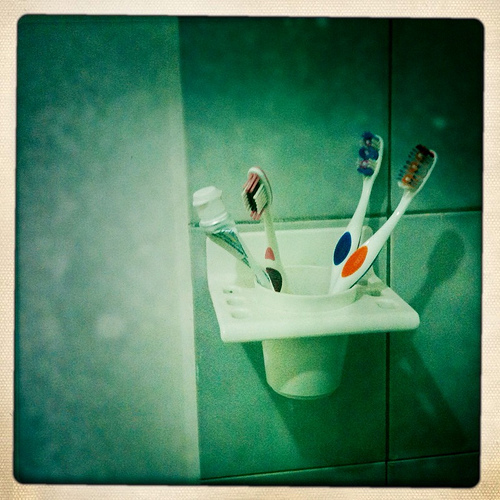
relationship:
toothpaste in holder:
[182, 184, 266, 294] [195, 229, 416, 411]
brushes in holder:
[237, 125, 440, 300] [195, 229, 416, 411]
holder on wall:
[195, 229, 416, 411] [16, 12, 485, 496]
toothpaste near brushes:
[182, 184, 266, 294] [237, 125, 440, 300]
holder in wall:
[195, 229, 416, 411] [16, 12, 485, 496]